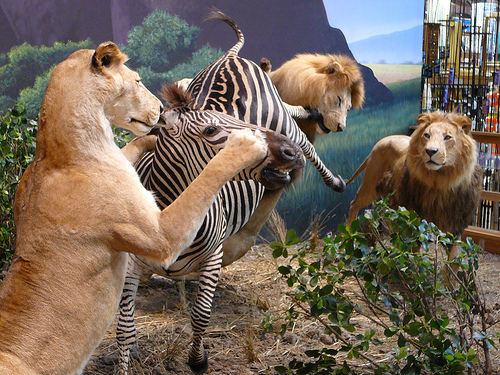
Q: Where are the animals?
A: In an exhibit.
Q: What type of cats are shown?
A: Lions.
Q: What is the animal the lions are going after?
A: Zebra.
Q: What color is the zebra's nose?
A: Black.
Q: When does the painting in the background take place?
A: Daytime.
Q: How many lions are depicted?
A: Three.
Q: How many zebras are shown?
A: One.